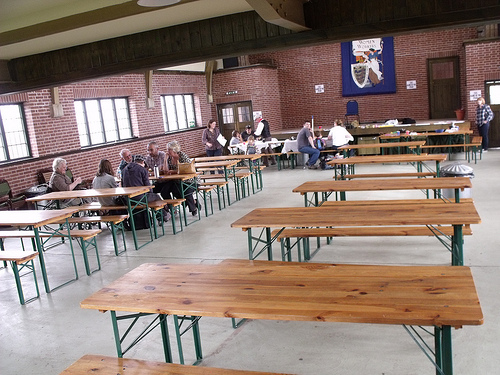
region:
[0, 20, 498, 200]
the red bricks on the wall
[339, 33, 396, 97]
the blue object on the wall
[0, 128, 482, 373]
the wooden table and benches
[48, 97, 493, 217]
the people in the room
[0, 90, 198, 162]
the windows on the wall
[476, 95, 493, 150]
the person standing alone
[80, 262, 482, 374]
the empty wooden table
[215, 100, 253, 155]
the wooden double doors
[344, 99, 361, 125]
the blue chair on the stage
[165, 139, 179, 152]
the gray hair on the woman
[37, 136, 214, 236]
people sitting around a table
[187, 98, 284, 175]
a group of people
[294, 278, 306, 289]
dark brown spot on the wood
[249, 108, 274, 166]
person standing by the table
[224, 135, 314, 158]
white tablecloth on the table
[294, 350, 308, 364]
dark spot on the floor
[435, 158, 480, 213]
silver trash can with a silver lid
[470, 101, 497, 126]
plaid long sleeve shirt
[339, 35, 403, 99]
decoration hanging on the wall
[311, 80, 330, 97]
sign on the wall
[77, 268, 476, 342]
a wooden table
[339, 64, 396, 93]
a picture on the wall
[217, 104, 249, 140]
the doors to the building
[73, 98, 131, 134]
a window in the building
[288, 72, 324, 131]
bricks on the wall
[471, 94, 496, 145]
a person standing up by a table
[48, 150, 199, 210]
people sitting at a table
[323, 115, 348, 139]
a person in a white shirt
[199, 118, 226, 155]
a person carrying a paper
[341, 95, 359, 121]
a blue chair